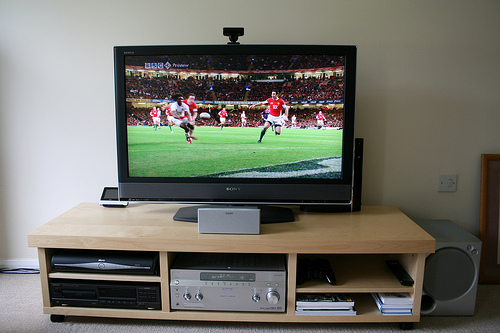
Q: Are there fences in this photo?
A: No, there are no fences.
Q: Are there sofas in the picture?
A: No, there are no sofas.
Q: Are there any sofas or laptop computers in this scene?
A: No, there are no sofas or laptop computers.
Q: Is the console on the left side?
A: Yes, the console is on the left of the image.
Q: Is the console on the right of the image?
A: No, the console is on the left of the image.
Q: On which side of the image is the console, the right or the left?
A: The console is on the left of the image.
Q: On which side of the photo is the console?
A: The console is on the left of the image.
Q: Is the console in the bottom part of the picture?
A: Yes, the console is in the bottom of the image.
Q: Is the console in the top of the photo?
A: No, the console is in the bottom of the image.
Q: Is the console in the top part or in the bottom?
A: The console is in the bottom of the image.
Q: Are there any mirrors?
A: No, there are no mirrors.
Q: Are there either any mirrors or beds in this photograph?
A: No, there are no mirrors or beds.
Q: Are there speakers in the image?
A: Yes, there is a speaker.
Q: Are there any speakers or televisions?
A: Yes, there is a speaker.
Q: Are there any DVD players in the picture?
A: Yes, there is a DVD player.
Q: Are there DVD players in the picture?
A: Yes, there is a DVD player.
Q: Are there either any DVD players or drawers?
A: Yes, there is a DVD player.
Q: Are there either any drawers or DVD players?
A: Yes, there is a DVD player.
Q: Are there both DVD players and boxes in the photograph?
A: Yes, there are both a DVD player and a box.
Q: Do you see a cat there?
A: No, there are no cats.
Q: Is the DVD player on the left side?
A: Yes, the DVD player is on the left of the image.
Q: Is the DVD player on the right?
A: No, the DVD player is on the left of the image.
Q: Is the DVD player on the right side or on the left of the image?
A: The DVD player is on the left of the image.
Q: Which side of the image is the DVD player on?
A: The DVD player is on the left of the image.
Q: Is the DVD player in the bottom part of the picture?
A: Yes, the DVD player is in the bottom of the image.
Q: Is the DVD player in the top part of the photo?
A: No, the DVD player is in the bottom of the image.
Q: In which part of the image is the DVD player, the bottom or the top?
A: The DVD player is in the bottom of the image.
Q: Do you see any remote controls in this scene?
A: Yes, there is a remote control.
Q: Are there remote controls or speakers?
A: Yes, there is a remote control.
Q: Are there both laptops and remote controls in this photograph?
A: No, there is a remote control but no laptops.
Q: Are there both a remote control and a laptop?
A: No, there is a remote control but no laptops.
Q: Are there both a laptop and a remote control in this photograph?
A: No, there is a remote control but no laptops.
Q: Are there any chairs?
A: No, there are no chairs.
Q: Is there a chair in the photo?
A: No, there are no chairs.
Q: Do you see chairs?
A: No, there are no chairs.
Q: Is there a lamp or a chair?
A: No, there are no chairs or lamps.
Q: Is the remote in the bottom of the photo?
A: Yes, the remote is in the bottom of the image.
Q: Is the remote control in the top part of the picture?
A: No, the remote control is in the bottom of the image.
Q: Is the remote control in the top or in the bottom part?
A: The remote control is in the bottom of the image.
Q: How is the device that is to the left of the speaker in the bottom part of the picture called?
A: The device is a remote control.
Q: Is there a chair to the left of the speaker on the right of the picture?
A: No, there is a remote control to the left of the speaker.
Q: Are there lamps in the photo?
A: No, there are no lamps.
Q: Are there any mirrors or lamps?
A: No, there are no lamps or mirrors.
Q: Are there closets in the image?
A: No, there are no closets.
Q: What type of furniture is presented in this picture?
A: The furniture is a shelf.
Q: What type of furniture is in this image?
A: The furniture is a shelf.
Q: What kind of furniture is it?
A: The piece of furniture is a shelf.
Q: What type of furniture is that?
A: This is a shelf.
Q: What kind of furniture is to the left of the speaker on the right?
A: The piece of furniture is a shelf.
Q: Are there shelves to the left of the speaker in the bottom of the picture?
A: Yes, there is a shelf to the left of the speaker.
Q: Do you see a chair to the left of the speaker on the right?
A: No, there is a shelf to the left of the speaker.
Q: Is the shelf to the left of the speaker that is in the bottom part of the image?
A: Yes, the shelf is to the left of the speaker.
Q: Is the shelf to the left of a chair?
A: No, the shelf is to the left of the speaker.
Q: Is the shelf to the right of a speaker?
A: No, the shelf is to the left of a speaker.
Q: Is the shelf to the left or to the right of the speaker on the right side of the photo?
A: The shelf is to the left of the speaker.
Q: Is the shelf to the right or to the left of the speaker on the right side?
A: The shelf is to the left of the speaker.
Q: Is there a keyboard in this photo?
A: No, there are no keyboards.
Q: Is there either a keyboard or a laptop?
A: No, there are no keyboards or laptops.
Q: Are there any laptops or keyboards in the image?
A: No, there are no keyboards or laptops.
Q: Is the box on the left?
A: Yes, the box is on the left of the image.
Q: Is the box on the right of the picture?
A: No, the box is on the left of the image.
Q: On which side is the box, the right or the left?
A: The box is on the left of the image.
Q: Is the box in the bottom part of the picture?
A: Yes, the box is in the bottom of the image.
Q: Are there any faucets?
A: No, there are no faucets.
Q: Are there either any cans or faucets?
A: No, there are no faucets or cans.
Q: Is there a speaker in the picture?
A: Yes, there is a speaker.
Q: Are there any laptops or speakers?
A: Yes, there is a speaker.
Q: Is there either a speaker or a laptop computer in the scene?
A: Yes, there is a speaker.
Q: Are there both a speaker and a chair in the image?
A: No, there is a speaker but no chairs.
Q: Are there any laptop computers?
A: No, there are no laptop computers.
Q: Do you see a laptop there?
A: No, there are no laptops.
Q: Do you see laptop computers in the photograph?
A: No, there are no laptop computers.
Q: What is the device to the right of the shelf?
A: The device is a speaker.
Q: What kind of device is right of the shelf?
A: The device is a speaker.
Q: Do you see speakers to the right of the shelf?
A: Yes, there is a speaker to the right of the shelf.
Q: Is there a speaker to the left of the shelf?
A: No, the speaker is to the right of the shelf.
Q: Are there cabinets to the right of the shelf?
A: No, there is a speaker to the right of the shelf.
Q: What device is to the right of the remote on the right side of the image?
A: The device is a speaker.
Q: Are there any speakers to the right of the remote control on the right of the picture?
A: Yes, there is a speaker to the right of the remote.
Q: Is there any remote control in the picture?
A: Yes, there is a remote control.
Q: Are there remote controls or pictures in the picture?
A: Yes, there is a remote control.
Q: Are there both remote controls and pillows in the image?
A: No, there is a remote control but no pillows.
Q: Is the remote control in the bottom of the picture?
A: Yes, the remote control is in the bottom of the image.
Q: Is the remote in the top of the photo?
A: No, the remote is in the bottom of the image.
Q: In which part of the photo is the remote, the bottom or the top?
A: The remote is in the bottom of the image.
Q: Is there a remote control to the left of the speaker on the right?
A: Yes, there is a remote control to the left of the speaker.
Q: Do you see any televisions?
A: Yes, there is a television.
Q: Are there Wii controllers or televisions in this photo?
A: Yes, there is a television.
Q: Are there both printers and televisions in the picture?
A: No, there is a television but no printers.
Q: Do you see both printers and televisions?
A: No, there is a television but no printers.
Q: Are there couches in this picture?
A: No, there are no couches.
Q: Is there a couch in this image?
A: No, there are no couches.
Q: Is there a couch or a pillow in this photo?
A: No, there are no couches or pillows.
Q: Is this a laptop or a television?
A: This is a television.